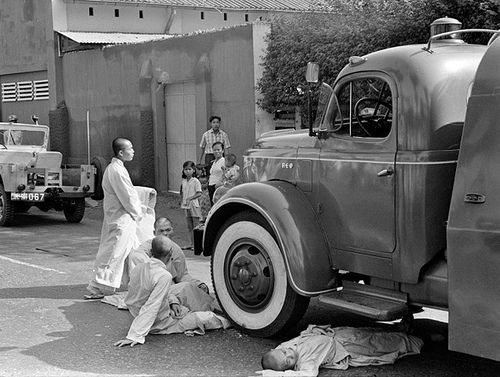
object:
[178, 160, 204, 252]
child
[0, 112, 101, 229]
jeep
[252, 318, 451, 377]
man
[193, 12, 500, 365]
truck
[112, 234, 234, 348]
man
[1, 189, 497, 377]
ground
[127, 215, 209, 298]
man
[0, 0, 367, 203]
building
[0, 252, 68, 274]
line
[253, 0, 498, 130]
tree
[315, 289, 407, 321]
running board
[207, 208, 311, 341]
tire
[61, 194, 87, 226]
tire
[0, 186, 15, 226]
tire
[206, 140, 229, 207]
woman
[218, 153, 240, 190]
baby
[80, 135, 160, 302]
man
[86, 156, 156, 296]
robe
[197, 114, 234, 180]
man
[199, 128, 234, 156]
shirt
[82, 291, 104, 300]
sandals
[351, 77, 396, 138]
window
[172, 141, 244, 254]
family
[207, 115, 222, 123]
hair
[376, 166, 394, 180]
handle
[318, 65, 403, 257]
door